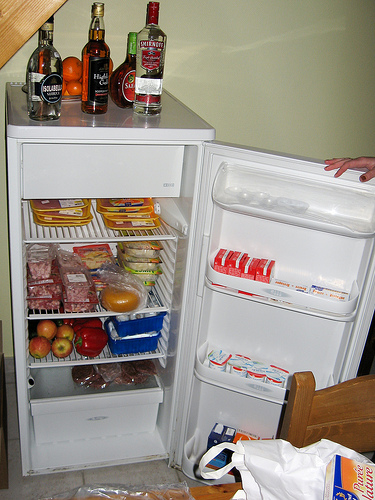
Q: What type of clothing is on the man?
A: Suit and tie.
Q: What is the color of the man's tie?
A: Black.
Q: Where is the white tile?
A: On the walls.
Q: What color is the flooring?
A: Dark gray.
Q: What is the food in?
A: A refrigerator.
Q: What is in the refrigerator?
A: Food.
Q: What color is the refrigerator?
A: White.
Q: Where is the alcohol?
A: On top of the fridge.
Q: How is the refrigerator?
A: It is open.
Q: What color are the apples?
A: Red.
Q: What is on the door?
A: A hand.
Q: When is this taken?
A: During the daytime.